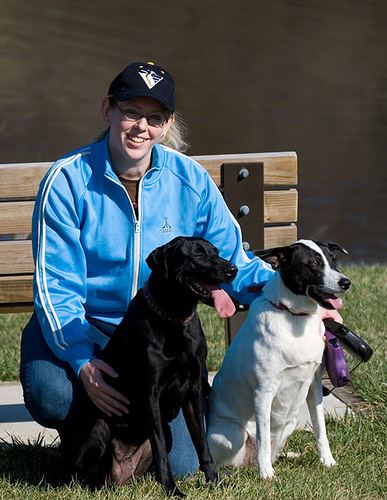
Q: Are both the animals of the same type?
A: Yes, all the animals are dogs.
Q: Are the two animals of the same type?
A: Yes, all the animals are dogs.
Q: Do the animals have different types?
A: No, all the animals are dogs.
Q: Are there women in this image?
A: Yes, there is a woman.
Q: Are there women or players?
A: Yes, there is a woman.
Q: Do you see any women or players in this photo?
A: Yes, there is a woman.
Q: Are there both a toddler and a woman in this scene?
A: No, there is a woman but no toddlers.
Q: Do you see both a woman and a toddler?
A: No, there is a woman but no toddlers.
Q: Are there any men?
A: No, there are no men.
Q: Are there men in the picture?
A: No, there are no men.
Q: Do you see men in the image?
A: No, there are no men.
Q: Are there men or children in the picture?
A: No, there are no men or children.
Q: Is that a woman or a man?
A: That is a woman.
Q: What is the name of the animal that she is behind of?
A: The animal is a dog.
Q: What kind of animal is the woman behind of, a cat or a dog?
A: The woman is behind a dog.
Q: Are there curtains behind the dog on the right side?
A: No, there is a woman behind the dog.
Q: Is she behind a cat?
A: No, the woman is behind the dog.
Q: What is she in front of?
A: The woman is in front of the bench.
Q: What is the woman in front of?
A: The woman is in front of the bench.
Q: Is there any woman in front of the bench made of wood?
A: Yes, there is a woman in front of the bench.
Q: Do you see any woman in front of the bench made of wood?
A: Yes, there is a woman in front of the bench.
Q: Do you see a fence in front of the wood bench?
A: No, there is a woman in front of the bench.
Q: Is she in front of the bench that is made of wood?
A: Yes, the woman is in front of the bench.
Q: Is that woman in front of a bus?
A: No, the woman is in front of the bench.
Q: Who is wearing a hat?
A: The woman is wearing a hat.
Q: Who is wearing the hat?
A: The woman is wearing a hat.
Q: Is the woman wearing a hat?
A: Yes, the woman is wearing a hat.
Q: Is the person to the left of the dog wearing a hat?
A: Yes, the woman is wearing a hat.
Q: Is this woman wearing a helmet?
A: No, the woman is wearing a hat.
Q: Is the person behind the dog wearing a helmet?
A: No, the woman is wearing a hat.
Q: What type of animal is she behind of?
A: The woman is behind the dog.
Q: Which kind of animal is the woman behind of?
A: The woman is behind the dog.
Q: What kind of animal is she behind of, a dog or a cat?
A: The woman is behind a dog.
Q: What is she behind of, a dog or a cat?
A: The woman is behind a dog.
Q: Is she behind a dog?
A: Yes, the woman is behind a dog.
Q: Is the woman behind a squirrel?
A: No, the woman is behind a dog.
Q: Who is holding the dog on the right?
A: The woman is holding the dog.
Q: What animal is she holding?
A: The woman is holding the dog.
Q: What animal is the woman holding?
A: The woman is holding the dog.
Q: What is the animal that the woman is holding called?
A: The animal is a dog.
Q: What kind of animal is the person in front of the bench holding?
A: The woman is holding the dog.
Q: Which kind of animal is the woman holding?
A: The woman is holding the dog.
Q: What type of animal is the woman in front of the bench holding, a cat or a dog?
A: The woman is holding a dog.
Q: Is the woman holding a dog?
A: Yes, the woman is holding a dog.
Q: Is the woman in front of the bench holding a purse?
A: No, the woman is holding a dog.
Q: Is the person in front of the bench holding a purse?
A: No, the woman is holding a dog.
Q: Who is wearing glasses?
A: The woman is wearing glasses.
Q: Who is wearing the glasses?
A: The woman is wearing glasses.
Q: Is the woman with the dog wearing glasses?
A: Yes, the woman is wearing glasses.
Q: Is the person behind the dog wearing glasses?
A: Yes, the woman is wearing glasses.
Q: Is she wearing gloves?
A: No, the woman is wearing glasses.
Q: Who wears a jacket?
A: The woman wears a jacket.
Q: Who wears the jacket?
A: The woman wears a jacket.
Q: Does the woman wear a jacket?
A: Yes, the woman wears a jacket.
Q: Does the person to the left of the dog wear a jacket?
A: Yes, the woman wears a jacket.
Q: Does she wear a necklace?
A: No, the woman wears a jacket.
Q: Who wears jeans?
A: The woman wears jeans.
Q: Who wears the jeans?
A: The woman wears jeans.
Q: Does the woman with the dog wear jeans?
A: Yes, the woman wears jeans.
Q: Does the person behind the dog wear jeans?
A: Yes, the woman wears jeans.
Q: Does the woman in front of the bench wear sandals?
A: No, the woman wears jeans.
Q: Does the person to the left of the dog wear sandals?
A: No, the woman wears jeans.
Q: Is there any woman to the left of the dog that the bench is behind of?
A: Yes, there is a woman to the left of the dog.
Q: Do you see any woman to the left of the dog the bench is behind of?
A: Yes, there is a woman to the left of the dog.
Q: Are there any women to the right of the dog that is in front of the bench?
A: No, the woman is to the left of the dog.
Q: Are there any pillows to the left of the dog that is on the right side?
A: No, there is a woman to the left of the dog.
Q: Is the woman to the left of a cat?
A: No, the woman is to the left of the dog.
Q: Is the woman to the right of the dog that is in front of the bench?
A: No, the woman is to the left of the dog.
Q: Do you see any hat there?
A: Yes, there is a hat.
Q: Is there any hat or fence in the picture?
A: Yes, there is a hat.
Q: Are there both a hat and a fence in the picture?
A: No, there is a hat but no fences.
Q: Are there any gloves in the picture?
A: No, there are no gloves.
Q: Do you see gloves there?
A: No, there are no gloves.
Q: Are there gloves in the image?
A: No, there are no gloves.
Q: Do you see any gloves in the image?
A: No, there are no gloves.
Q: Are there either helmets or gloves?
A: No, there are no gloves or helmets.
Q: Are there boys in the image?
A: No, there are no boys.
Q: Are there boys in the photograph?
A: No, there are no boys.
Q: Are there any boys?
A: No, there are no boys.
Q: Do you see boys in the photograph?
A: No, there are no boys.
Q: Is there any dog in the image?
A: Yes, there is a dog.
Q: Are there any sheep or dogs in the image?
A: Yes, there is a dog.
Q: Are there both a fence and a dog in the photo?
A: No, there is a dog but no fences.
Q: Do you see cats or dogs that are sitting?
A: Yes, the dog is sitting.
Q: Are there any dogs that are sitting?
A: Yes, there is a dog that is sitting.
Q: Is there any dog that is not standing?
A: Yes, there is a dog that is sitting.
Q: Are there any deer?
A: No, there are no deer.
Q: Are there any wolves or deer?
A: No, there are no deer or wolves.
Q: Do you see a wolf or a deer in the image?
A: No, there are no deer or wolves.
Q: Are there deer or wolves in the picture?
A: No, there are no deer or wolves.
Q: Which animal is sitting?
A: The animal is a dog.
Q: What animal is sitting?
A: The animal is a dog.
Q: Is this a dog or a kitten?
A: This is a dog.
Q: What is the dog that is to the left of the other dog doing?
A: The dog is sitting.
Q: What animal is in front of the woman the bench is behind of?
A: The dog is in front of the woman.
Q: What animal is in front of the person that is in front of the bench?
A: The dog is in front of the woman.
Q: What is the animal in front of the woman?
A: The animal is a dog.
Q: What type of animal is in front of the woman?
A: The animal is a dog.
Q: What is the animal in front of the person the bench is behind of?
A: The animal is a dog.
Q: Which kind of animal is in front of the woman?
A: The animal is a dog.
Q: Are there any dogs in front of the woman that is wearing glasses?
A: Yes, there is a dog in front of the woman.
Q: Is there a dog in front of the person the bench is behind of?
A: Yes, there is a dog in front of the woman.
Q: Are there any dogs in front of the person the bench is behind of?
A: Yes, there is a dog in front of the woman.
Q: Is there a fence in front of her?
A: No, there is a dog in front of the woman.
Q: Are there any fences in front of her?
A: No, there is a dog in front of the woman.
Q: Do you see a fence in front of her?
A: No, there is a dog in front of the woman.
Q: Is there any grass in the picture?
A: Yes, there is grass.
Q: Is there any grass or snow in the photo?
A: Yes, there is grass.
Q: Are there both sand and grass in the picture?
A: No, there is grass but no sand.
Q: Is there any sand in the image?
A: No, there is no sand.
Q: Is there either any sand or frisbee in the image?
A: No, there are no sand or frisbees.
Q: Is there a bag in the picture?
A: No, there are no bags.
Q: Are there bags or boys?
A: No, there are no bags or boys.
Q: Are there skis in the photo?
A: No, there are no skis.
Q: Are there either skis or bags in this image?
A: No, there are no skis or bags.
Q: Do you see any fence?
A: No, there are no fences.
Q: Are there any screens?
A: No, there are no screens.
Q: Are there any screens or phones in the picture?
A: No, there are no screens or phones.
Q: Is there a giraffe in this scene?
A: No, there are no giraffes.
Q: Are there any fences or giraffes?
A: No, there are no giraffes or fences.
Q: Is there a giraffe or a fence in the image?
A: No, there are no giraffes or fences.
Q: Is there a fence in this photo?
A: No, there are no fences.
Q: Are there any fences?
A: No, there are no fences.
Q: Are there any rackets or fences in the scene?
A: No, there are no fences or rackets.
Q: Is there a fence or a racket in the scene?
A: No, there are no fences or rackets.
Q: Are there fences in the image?
A: No, there are no fences.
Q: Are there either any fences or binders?
A: No, there are no fences or binders.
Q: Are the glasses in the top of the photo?
A: Yes, the glasses are in the top of the image.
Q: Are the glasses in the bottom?
A: No, the glasses are in the top of the image.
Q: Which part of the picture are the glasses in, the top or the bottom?
A: The glasses are in the top of the image.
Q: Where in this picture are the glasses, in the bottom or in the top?
A: The glasses are in the top of the image.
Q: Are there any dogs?
A: Yes, there is a dog.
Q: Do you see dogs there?
A: Yes, there is a dog.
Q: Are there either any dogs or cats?
A: Yes, there is a dog.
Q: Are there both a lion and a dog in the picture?
A: No, there is a dog but no lions.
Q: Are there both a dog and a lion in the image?
A: No, there is a dog but no lions.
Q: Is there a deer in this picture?
A: No, there is no deer.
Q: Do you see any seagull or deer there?
A: No, there are no deer or seagulls.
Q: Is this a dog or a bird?
A: This is a dog.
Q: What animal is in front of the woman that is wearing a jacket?
A: The dog is in front of the woman.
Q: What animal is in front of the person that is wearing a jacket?
A: The dog is in front of the woman.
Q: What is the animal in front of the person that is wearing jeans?
A: The animal is a dog.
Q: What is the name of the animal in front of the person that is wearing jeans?
A: The animal is a dog.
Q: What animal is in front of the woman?
A: The animal is a dog.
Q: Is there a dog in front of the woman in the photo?
A: Yes, there is a dog in front of the woman.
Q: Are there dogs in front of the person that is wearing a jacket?
A: Yes, there is a dog in front of the woman.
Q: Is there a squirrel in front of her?
A: No, there is a dog in front of the woman.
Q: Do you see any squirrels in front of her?
A: No, there is a dog in front of the woman.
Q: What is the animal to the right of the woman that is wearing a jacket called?
A: The animal is a dog.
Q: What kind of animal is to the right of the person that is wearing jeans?
A: The animal is a dog.